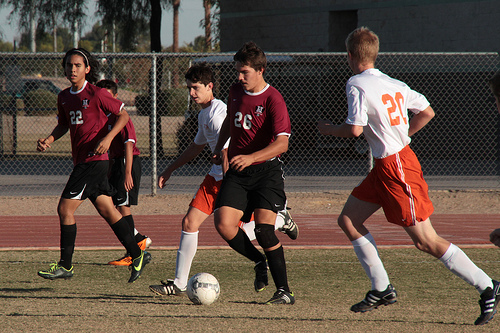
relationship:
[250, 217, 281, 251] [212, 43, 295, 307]
knee brace on boy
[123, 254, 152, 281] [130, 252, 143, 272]
shoe with nike check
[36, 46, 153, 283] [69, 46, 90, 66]
boy wearing band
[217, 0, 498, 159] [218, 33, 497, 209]
building behind fence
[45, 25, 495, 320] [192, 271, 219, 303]
group playing ball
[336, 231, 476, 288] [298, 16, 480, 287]
socks on player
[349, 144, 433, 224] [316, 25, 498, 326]
shorts on player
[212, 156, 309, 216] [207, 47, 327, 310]
shorts on player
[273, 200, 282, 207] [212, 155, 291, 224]
logo on shorts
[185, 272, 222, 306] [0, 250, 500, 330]
ball on field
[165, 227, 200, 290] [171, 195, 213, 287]
sock on leg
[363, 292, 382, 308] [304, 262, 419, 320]
lines on shoe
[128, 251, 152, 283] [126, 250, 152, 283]
shoe on side of shoe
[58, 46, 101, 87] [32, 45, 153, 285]
head part of boy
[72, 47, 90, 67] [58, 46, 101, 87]
band worn on head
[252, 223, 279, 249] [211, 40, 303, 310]
knee brace worn by boy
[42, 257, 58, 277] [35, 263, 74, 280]
laces part of shoe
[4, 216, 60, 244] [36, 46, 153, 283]
red track behind boy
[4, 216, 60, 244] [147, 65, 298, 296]
red track behind soccer player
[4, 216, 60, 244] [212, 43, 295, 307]
red track behind boy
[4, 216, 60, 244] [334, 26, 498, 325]
red track behind soccer player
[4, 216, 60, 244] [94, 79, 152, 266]
red track behind player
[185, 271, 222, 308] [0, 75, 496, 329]
ball rolling on ground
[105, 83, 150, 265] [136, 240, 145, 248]
player wearing shoes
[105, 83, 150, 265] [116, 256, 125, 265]
player wearing shoes